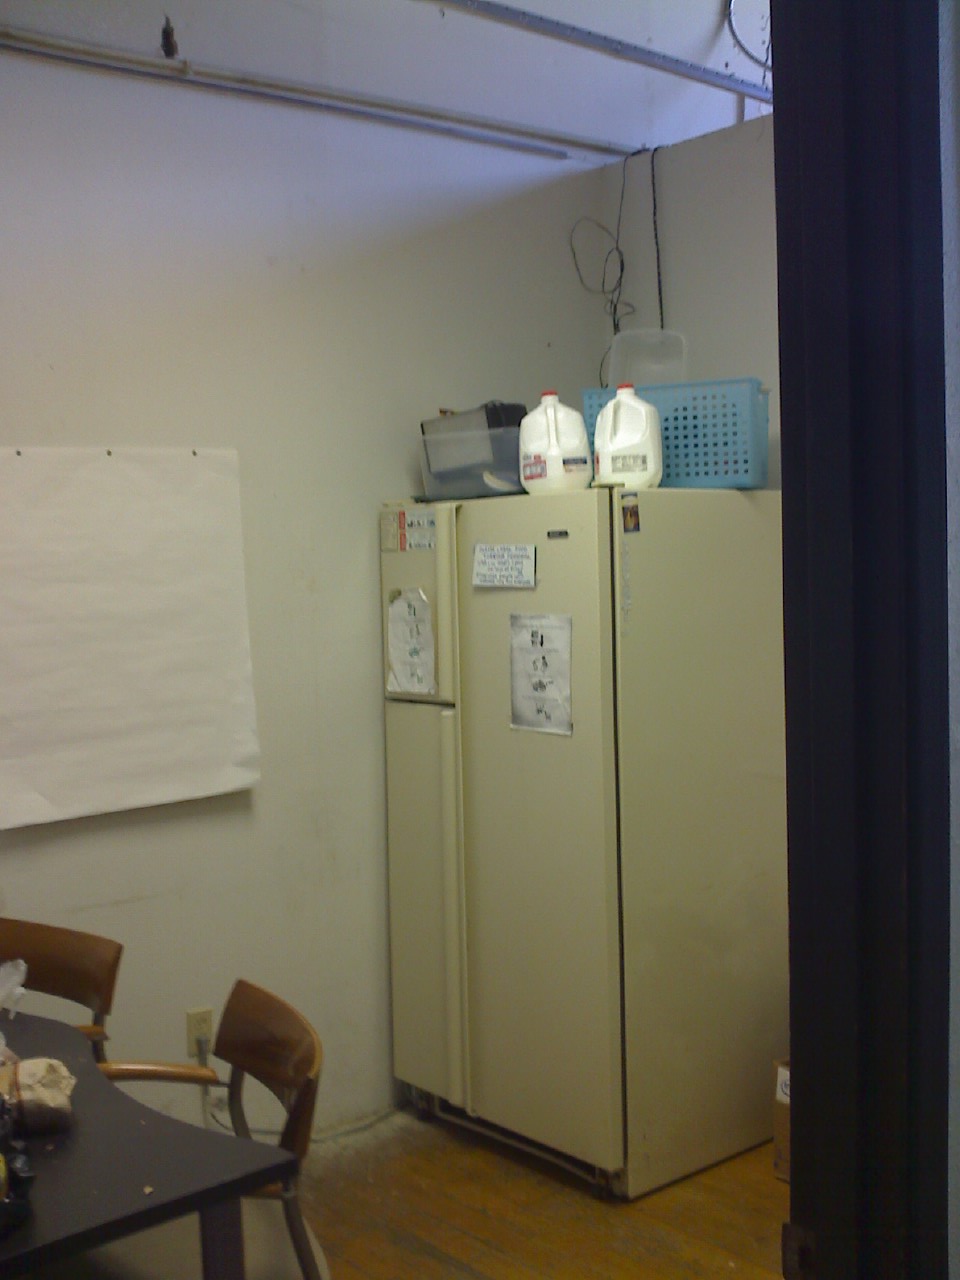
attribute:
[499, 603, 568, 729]
paper — piece of paper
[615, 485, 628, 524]
paper — piece of paper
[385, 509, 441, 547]
paper — piece of paper